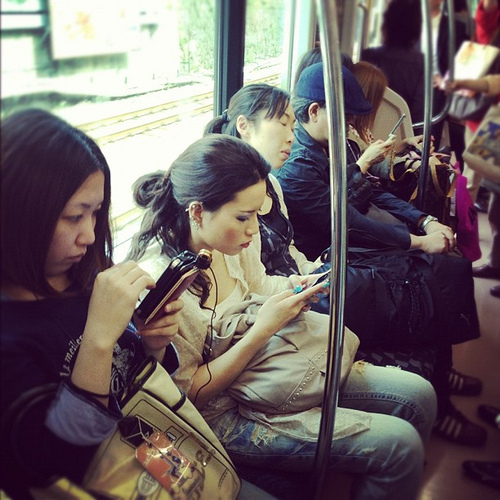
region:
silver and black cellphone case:
[129, 245, 205, 337]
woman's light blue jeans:
[206, 352, 456, 497]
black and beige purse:
[65, 372, 259, 498]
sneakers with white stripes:
[435, 379, 493, 456]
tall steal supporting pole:
[296, 4, 388, 471]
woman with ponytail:
[124, 129, 276, 255]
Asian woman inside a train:
[194, 69, 491, 387]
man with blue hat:
[287, 52, 378, 143]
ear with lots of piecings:
[182, 198, 214, 236]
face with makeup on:
[213, 171, 272, 268]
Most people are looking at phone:
[42, 68, 497, 420]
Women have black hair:
[6, 92, 301, 357]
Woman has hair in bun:
[113, 134, 263, 285]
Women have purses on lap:
[49, 262, 358, 498]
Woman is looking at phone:
[28, 167, 205, 380]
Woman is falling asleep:
[211, 72, 345, 192]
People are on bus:
[4, 4, 481, 492]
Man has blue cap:
[267, 62, 381, 154]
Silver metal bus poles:
[320, 8, 350, 493]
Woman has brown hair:
[332, 52, 399, 147]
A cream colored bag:
[60, 362, 252, 498]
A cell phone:
[139, 237, 193, 319]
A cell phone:
[306, 265, 345, 291]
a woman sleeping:
[213, 65, 320, 304]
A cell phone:
[381, 105, 411, 153]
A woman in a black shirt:
[10, 108, 186, 494]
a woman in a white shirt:
[122, 135, 298, 408]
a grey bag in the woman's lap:
[225, 292, 360, 422]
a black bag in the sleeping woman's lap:
[299, 251, 446, 328]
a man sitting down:
[278, 56, 492, 443]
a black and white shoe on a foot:
[427, 405, 485, 445]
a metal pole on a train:
[305, 0, 370, 495]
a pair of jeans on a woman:
[225, 355, 440, 495]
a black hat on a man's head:
[295, 60, 375, 110]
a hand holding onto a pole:
[442, 70, 487, 95]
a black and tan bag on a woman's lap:
[65, 352, 241, 494]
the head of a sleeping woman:
[210, 80, 300, 180]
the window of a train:
[1, 3, 331, 260]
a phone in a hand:
[377, 105, 409, 155]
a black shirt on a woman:
[4, 272, 148, 489]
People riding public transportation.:
[9, 0, 497, 495]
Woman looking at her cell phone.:
[0, 108, 209, 404]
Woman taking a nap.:
[206, 75, 303, 180]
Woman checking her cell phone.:
[142, 129, 354, 407]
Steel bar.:
[307, 45, 354, 496]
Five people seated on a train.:
[2, 47, 465, 497]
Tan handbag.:
[213, 283, 360, 422]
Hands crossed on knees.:
[402, 205, 462, 265]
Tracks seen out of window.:
[40, 85, 229, 134]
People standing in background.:
[404, 0, 498, 289]